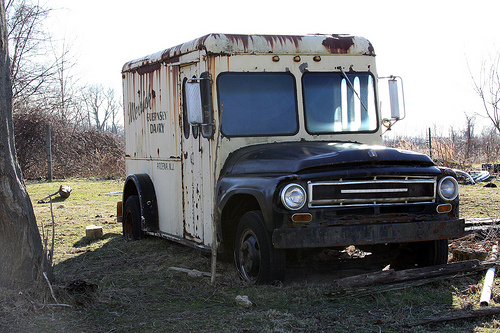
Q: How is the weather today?
A: It is clear.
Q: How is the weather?
A: It is clear.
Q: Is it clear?
A: Yes, it is clear.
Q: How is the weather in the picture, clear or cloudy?
A: It is clear.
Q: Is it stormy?
A: No, it is clear.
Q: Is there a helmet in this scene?
A: No, there are no helmets.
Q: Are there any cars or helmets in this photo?
A: No, there are no helmets or cars.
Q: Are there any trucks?
A: Yes, there is a truck.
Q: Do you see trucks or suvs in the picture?
A: Yes, there is a truck.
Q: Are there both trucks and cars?
A: No, there is a truck but no cars.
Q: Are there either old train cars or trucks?
A: Yes, there is an old truck.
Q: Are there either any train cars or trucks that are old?
A: Yes, the truck is old.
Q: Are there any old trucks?
A: Yes, there is an old truck.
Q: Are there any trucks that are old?
A: Yes, there is a truck that is old.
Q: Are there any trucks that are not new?
A: Yes, there is a old truck.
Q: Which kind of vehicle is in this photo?
A: The vehicle is a truck.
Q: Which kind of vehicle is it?
A: The vehicle is a truck.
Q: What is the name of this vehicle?
A: This is a truck.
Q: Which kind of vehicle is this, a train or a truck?
A: This is a truck.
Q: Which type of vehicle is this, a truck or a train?
A: This is a truck.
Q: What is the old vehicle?
A: The vehicle is a truck.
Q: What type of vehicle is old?
A: The vehicle is a truck.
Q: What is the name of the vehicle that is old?
A: The vehicle is a truck.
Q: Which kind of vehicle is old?
A: The vehicle is a truck.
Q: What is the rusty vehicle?
A: The vehicle is a truck.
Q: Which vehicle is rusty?
A: The vehicle is a truck.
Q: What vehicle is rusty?
A: The vehicle is a truck.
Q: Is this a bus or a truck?
A: This is a truck.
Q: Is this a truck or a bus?
A: This is a truck.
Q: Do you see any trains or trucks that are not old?
A: No, there is a truck but it is old.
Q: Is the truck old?
A: Yes, the truck is old.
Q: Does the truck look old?
A: Yes, the truck is old.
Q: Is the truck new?
A: No, the truck is old.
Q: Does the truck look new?
A: No, the truck is old.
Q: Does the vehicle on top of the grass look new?
A: No, the truck is old.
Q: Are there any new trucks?
A: No, there is a truck but it is old.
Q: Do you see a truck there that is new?
A: No, there is a truck but it is old.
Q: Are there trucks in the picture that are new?
A: No, there is a truck but it is old.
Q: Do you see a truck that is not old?
A: No, there is a truck but it is old.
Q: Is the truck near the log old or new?
A: The truck is old.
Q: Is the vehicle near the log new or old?
A: The truck is old.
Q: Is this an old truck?
A: Yes, this is an old truck.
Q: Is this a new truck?
A: No, this is an old truck.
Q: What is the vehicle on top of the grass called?
A: The vehicle is a truck.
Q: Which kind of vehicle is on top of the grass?
A: The vehicle is a truck.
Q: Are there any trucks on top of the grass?
A: Yes, there is a truck on top of the grass.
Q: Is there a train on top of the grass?
A: No, there is a truck on top of the grass.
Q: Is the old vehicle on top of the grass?
A: Yes, the truck is on top of the grass.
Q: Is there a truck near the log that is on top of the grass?
A: Yes, there is a truck near the log.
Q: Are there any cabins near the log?
A: No, there is a truck near the log.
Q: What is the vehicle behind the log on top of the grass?
A: The vehicle is a truck.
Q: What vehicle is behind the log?
A: The vehicle is a truck.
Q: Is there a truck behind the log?
A: Yes, there is a truck behind the log.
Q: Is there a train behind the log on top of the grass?
A: No, there is a truck behind the log.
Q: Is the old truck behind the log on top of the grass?
A: Yes, the truck is behind the log.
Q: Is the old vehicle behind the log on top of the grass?
A: Yes, the truck is behind the log.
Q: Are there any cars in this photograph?
A: No, there are no cars.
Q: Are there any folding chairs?
A: No, there are no folding chairs.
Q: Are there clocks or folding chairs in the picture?
A: No, there are no folding chairs or clocks.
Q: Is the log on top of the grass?
A: Yes, the log is on top of the grass.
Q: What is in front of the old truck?
A: The log is in front of the truck.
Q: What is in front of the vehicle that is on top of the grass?
A: The log is in front of the truck.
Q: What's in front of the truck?
A: The log is in front of the truck.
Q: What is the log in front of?
A: The log is in front of the truck.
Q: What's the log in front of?
A: The log is in front of the truck.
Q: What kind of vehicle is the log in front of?
A: The log is in front of the truck.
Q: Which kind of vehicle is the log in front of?
A: The log is in front of the truck.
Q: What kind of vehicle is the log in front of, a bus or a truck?
A: The log is in front of a truck.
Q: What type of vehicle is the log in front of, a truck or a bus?
A: The log is in front of a truck.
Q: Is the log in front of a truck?
A: Yes, the log is in front of a truck.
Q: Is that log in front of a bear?
A: No, the log is in front of a truck.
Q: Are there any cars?
A: No, there are no cars.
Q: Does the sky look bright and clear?
A: Yes, the sky is bright and clear.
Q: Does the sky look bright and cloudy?
A: No, the sky is bright but clear.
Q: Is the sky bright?
A: Yes, the sky is bright.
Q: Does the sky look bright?
A: Yes, the sky is bright.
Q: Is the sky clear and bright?
A: Yes, the sky is clear and bright.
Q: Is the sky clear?
A: Yes, the sky is clear.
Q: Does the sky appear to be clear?
A: Yes, the sky is clear.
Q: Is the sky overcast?
A: No, the sky is clear.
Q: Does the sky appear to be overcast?
A: No, the sky is clear.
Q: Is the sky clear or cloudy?
A: The sky is clear.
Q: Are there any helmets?
A: No, there are no helmets.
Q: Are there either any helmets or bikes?
A: No, there are no helmets or bikes.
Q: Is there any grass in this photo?
A: Yes, there is grass.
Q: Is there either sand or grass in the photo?
A: Yes, there is grass.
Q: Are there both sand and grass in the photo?
A: No, there is grass but no sand.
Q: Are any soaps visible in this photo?
A: No, there are no soaps.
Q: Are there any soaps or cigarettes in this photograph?
A: No, there are no soaps or cigarettes.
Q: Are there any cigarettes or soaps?
A: No, there are no soaps or cigarettes.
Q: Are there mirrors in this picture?
A: Yes, there is a mirror.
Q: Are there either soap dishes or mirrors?
A: Yes, there is a mirror.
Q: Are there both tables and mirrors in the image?
A: No, there is a mirror but no tables.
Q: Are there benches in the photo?
A: No, there are no benches.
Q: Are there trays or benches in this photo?
A: No, there are no benches or trays.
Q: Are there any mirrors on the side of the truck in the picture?
A: Yes, there is a mirror on the side of the truck.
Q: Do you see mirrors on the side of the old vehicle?
A: Yes, there is a mirror on the side of the truck.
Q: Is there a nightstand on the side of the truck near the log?
A: No, there is a mirror on the side of the truck.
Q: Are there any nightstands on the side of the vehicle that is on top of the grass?
A: No, there is a mirror on the side of the truck.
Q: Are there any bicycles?
A: No, there are no bicycles.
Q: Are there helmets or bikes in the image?
A: No, there are no bikes or helmets.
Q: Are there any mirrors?
A: Yes, there is a mirror.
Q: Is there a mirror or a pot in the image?
A: Yes, there is a mirror.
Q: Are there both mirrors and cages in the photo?
A: No, there is a mirror but no cages.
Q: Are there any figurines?
A: No, there are no figurines.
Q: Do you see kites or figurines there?
A: No, there are no figurines or kites.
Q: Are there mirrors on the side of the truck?
A: Yes, there is a mirror on the side of the truck.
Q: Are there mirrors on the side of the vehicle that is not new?
A: Yes, there is a mirror on the side of the truck.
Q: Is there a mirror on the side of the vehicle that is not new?
A: Yes, there is a mirror on the side of the truck.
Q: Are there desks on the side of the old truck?
A: No, there is a mirror on the side of the truck.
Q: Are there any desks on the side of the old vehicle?
A: No, there is a mirror on the side of the truck.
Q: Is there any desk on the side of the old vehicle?
A: No, there is a mirror on the side of the truck.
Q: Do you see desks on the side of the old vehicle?
A: No, there is a mirror on the side of the truck.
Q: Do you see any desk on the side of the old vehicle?
A: No, there is a mirror on the side of the truck.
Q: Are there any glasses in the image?
A: No, there are no glasses.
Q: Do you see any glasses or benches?
A: No, there are no glasses or benches.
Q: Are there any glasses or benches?
A: No, there are no glasses or benches.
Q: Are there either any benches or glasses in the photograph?
A: No, there are no glasses or benches.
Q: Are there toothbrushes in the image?
A: No, there are no toothbrushes.